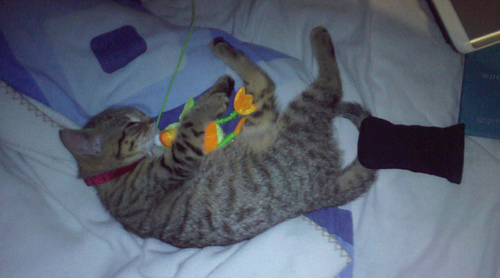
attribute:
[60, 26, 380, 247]
cat — grey, sleeping, striped, tabby, lying, young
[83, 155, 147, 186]
collar — red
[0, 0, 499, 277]
bed — white, blue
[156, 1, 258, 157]
toy — orange, green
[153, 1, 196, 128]
stick — green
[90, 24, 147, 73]
square — blue